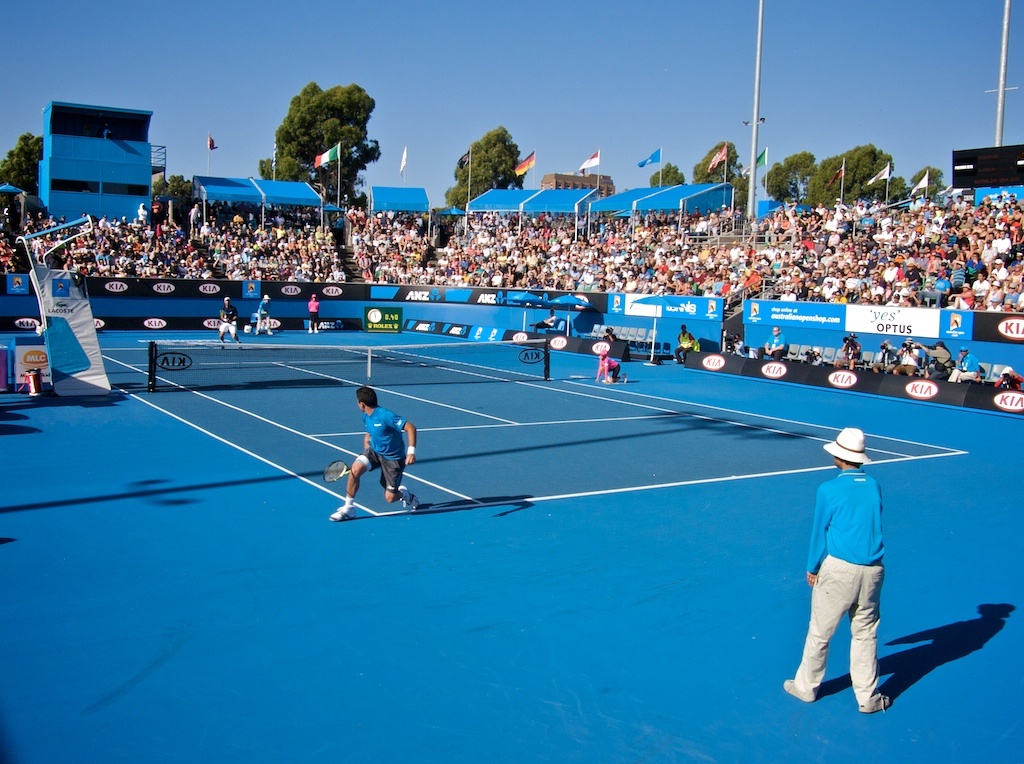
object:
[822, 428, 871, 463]
hat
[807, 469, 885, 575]
shirt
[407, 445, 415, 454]
wristband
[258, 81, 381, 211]
tree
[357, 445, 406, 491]
shorts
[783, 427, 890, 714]
man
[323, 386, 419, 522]
person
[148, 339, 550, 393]
net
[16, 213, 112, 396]
booth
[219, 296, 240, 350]
man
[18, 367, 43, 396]
trash can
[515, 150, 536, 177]
flag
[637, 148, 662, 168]
flag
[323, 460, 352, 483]
racket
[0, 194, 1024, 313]
crowd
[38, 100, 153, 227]
area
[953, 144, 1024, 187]
scoreboard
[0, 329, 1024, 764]
court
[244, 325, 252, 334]
ball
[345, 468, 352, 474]
hands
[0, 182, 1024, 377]
stands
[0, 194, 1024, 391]
crowd